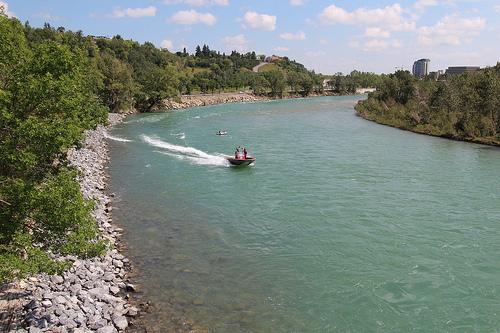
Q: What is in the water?
A: Rocks and dirt.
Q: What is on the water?
A: A boat.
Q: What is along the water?
A: Rocks and trees.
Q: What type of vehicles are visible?
A: Boats.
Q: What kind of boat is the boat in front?
A: Motor boat.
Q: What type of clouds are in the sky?
A: Cumulus.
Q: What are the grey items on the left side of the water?
A: Rocks.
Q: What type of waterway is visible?
A: Canal.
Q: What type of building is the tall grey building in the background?
A: High rise.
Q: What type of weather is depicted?
A: Partly cloudy.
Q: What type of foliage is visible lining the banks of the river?
A: Trees and shrubs.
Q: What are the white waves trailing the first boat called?
A: A wake.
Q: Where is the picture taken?
A: At a body of water.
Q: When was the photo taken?
A: Day time.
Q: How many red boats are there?
A: One.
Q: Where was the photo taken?
A: The river.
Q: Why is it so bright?
A: Sunny.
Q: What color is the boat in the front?
A: Red.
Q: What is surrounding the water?
A: Rocks.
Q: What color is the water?
A: Green.